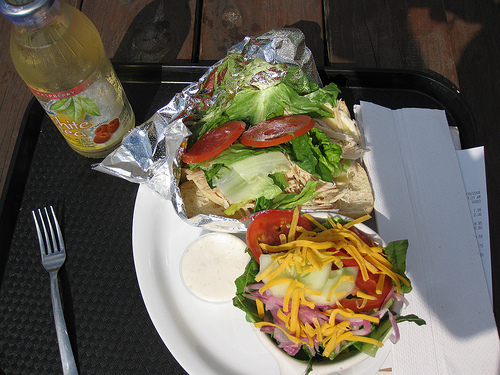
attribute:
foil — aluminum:
[88, 24, 345, 239]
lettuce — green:
[203, 62, 332, 212]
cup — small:
[177, 230, 248, 303]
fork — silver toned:
[29, 205, 80, 374]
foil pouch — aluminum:
[91, 28, 349, 231]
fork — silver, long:
[20, 206, 99, 373]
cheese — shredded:
[253, 321, 303, 347]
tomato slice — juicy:
[183, 122, 242, 161]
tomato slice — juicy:
[240, 113, 312, 145]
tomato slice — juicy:
[245, 210, 292, 263]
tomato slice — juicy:
[295, 213, 310, 228]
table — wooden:
[3, 3, 496, 130]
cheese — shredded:
[254, 293, 269, 318]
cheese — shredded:
[255, 284, 322, 348]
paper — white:
[350, 98, 497, 373]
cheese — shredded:
[301, 244, 338, 265]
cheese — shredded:
[242, 261, 310, 318]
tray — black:
[5, 66, 497, 368]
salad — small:
[282, 253, 352, 325]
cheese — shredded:
[331, 219, 414, 295]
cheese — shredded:
[287, 249, 369, 273]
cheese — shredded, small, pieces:
[289, 222, 375, 268]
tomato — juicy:
[338, 245, 398, 316]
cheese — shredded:
[259, 237, 403, 337]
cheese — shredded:
[246, 195, 418, 362]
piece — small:
[286, 204, 303, 242]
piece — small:
[343, 240, 370, 281]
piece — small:
[323, 271, 357, 303]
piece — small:
[253, 275, 305, 290]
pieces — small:
[261, 211, 402, 290]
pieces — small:
[260, 221, 400, 288]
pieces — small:
[254, 208, 408, 295]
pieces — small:
[244, 199, 412, 304]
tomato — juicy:
[245, 197, 321, 263]